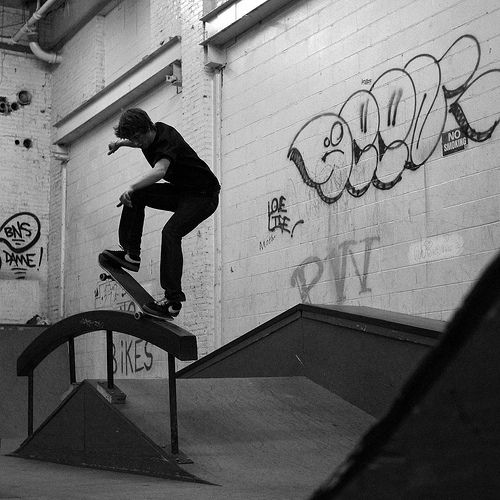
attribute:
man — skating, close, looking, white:
[105, 104, 221, 313]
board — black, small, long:
[95, 246, 163, 329]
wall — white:
[36, 0, 500, 321]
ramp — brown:
[0, 310, 476, 500]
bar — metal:
[165, 351, 183, 461]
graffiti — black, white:
[287, 34, 484, 201]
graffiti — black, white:
[291, 33, 484, 222]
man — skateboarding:
[104, 96, 222, 325]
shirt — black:
[137, 123, 226, 207]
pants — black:
[118, 177, 222, 295]